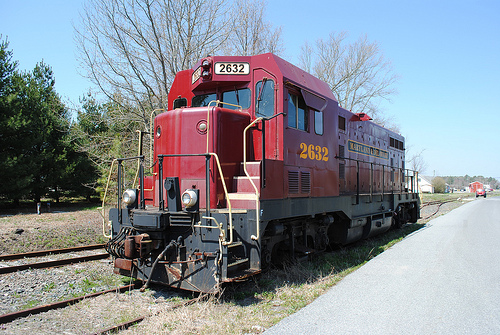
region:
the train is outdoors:
[101, 57, 426, 293]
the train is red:
[108, 54, 422, 294]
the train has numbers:
[298, 145, 330, 160]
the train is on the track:
[106, 46, 408, 312]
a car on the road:
[476, 189, 483, 198]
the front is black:
[105, 204, 260, 286]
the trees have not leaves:
[87, 0, 383, 147]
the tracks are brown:
[1, 242, 203, 333]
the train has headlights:
[124, 191, 197, 206]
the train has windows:
[170, 89, 324, 137]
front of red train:
[93, 60, 285, 288]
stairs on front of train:
[88, 135, 235, 312]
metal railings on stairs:
[143, 150, 224, 171]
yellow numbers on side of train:
[289, 131, 336, 166]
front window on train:
[190, 85, 262, 106]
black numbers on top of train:
[214, 63, 251, 77]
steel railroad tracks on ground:
[57, 286, 112, 333]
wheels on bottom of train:
[286, 220, 350, 258]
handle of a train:
[203, 138, 233, 262]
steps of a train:
[202, 203, 273, 275]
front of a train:
[137, 103, 271, 207]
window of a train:
[176, 65, 283, 120]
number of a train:
[212, 58, 263, 86]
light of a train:
[197, 52, 221, 80]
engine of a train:
[149, 96, 266, 204]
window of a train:
[279, 82, 353, 133]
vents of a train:
[275, 165, 329, 200]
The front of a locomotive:
[160, 90, 270, 274]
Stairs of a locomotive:
[235, 179, 247, 204]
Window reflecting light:
[226, 92, 236, 101]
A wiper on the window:
[257, 88, 261, 100]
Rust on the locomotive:
[173, 269, 178, 276]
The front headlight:
[180, 190, 196, 205]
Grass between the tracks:
[104, 297, 150, 310]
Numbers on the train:
[301, 145, 327, 160]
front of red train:
[92, 43, 280, 288]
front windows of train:
[197, 75, 276, 112]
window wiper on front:
[252, 71, 269, 109]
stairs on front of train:
[211, 171, 282, 275]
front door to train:
[252, 64, 273, 154]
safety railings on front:
[148, 138, 226, 189]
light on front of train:
[181, 189, 193, 210]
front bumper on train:
[100, 241, 202, 303]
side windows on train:
[280, 75, 325, 134]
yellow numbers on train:
[295, 127, 331, 167]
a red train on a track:
[99, 51, 421, 298]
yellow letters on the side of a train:
[296, 139, 331, 166]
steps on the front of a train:
[216, 154, 263, 216]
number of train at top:
[210, 52, 252, 83]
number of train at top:
[212, 55, 265, 77]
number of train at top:
[209, 54, 264, 83]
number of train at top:
[204, 57, 271, 83]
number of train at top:
[209, 51, 263, 79]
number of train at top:
[201, 48, 256, 84]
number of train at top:
[198, 48, 271, 87]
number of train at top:
[206, 49, 268, 80]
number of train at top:
[204, 55, 264, 79]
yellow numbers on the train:
[295, 139, 329, 168]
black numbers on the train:
[212, 57, 254, 81]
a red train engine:
[92, 49, 423, 303]